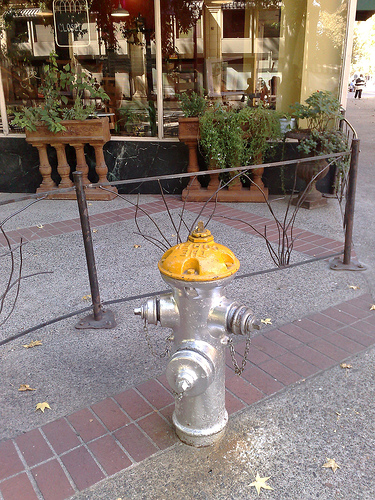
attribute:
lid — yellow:
[156, 222, 240, 282]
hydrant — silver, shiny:
[133, 271, 265, 447]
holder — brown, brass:
[22, 116, 119, 200]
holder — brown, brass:
[175, 117, 268, 202]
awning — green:
[349, 0, 370, 30]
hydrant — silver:
[136, 209, 259, 452]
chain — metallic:
[227, 324, 252, 384]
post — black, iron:
[333, 121, 371, 283]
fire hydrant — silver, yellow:
[131, 217, 264, 448]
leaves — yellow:
[245, 454, 339, 496]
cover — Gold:
[162, 228, 215, 290]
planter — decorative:
[295, 95, 350, 212]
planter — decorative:
[181, 102, 281, 200]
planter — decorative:
[20, 72, 115, 197]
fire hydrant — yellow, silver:
[130, 193, 276, 453]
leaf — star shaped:
[245, 472, 272, 493]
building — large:
[1, 1, 357, 195]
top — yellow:
[157, 221, 239, 279]